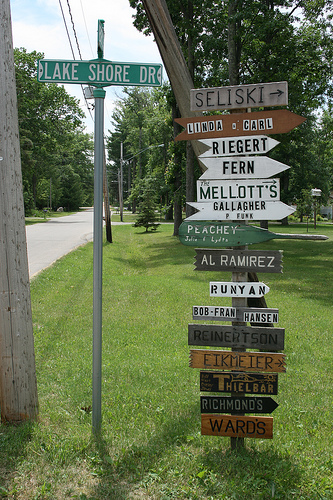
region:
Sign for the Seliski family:
[188, 86, 287, 105]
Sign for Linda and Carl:
[172, 116, 302, 134]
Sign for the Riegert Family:
[196, 139, 276, 152]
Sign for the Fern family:
[198, 158, 289, 175]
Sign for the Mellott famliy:
[194, 178, 282, 199]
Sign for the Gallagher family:
[190, 198, 300, 221]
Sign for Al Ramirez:
[192, 246, 290, 271]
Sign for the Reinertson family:
[188, 325, 282, 349]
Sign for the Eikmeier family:
[186, 348, 285, 373]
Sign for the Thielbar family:
[195, 368, 280, 396]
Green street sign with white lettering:
[37, 17, 163, 431]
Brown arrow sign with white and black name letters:
[170, 108, 307, 140]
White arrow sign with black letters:
[192, 134, 280, 158]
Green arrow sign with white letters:
[178, 221, 279, 248]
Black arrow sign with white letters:
[198, 395, 276, 412]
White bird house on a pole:
[307, 185, 318, 225]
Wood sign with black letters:
[197, 411, 269, 437]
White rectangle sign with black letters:
[193, 177, 277, 197]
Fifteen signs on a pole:
[171, 77, 304, 445]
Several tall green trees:
[129, 0, 331, 236]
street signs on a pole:
[36, 17, 163, 428]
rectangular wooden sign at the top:
[187, 80, 289, 111]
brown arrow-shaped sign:
[175, 111, 307, 140]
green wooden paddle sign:
[173, 215, 330, 248]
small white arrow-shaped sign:
[208, 277, 271, 300]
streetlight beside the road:
[116, 139, 164, 222]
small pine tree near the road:
[132, 182, 163, 234]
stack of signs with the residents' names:
[175, 81, 295, 440]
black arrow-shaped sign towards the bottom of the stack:
[197, 396, 281, 415]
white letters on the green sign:
[42, 61, 157, 84]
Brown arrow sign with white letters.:
[193, 390, 286, 415]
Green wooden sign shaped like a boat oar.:
[174, 215, 331, 253]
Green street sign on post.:
[33, 44, 169, 95]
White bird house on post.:
[309, 185, 322, 228]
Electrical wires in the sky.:
[55, 0, 87, 48]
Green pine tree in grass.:
[133, 174, 164, 238]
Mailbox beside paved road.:
[37, 201, 52, 221]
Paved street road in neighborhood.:
[25, 192, 95, 274]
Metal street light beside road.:
[112, 132, 168, 225]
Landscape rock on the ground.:
[53, 203, 65, 214]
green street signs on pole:
[35, 18, 161, 89]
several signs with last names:
[174, 79, 303, 447]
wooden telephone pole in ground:
[1, 1, 40, 428]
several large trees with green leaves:
[13, 0, 332, 244]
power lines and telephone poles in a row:
[55, 0, 129, 243]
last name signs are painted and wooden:
[174, 79, 306, 453]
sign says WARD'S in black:
[200, 414, 274, 438]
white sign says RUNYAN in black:
[206, 278, 272, 299]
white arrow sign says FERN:
[199, 157, 291, 178]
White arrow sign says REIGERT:
[199, 133, 281, 154]